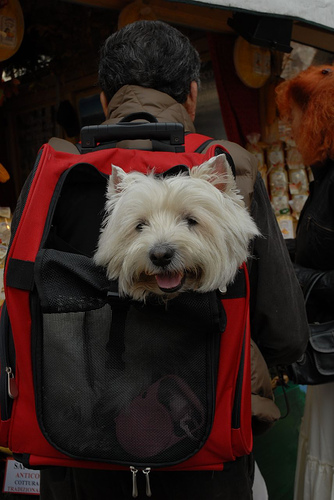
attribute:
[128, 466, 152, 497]
zipper — metal 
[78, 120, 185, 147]
handle — black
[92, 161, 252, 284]
dog — white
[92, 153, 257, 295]
dog — white , long haired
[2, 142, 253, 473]
backpack — red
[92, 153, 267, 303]
dog — white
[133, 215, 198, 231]
eyes — Black 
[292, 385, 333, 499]
skirt — white, lace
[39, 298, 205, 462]
pocket — mesh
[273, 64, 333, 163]
hair — red, fussy, brown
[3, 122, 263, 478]
backpack — black, red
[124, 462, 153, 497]
zipper — silver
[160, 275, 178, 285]
tougne — pink 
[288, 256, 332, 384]
bag — black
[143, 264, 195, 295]
mouth — open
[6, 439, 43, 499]
sign — red, white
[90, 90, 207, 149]
jacket — brown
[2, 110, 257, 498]
bag — red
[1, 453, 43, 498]
sign — red, white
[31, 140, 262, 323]
backpack — red and black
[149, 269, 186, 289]
tongue — pink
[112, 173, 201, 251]
dog — white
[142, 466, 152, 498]
zipper pull — silver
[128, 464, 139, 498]
zipper pull — silver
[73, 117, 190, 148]
handle — black